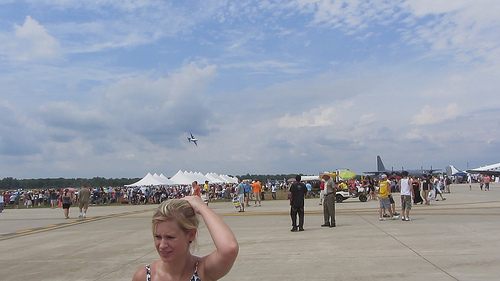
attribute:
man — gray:
[374, 172, 398, 221]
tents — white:
[127, 165, 243, 188]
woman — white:
[130, 192, 240, 279]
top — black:
[143, 256, 202, 279]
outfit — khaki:
[75, 175, 110, 220]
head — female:
[148, 197, 200, 264]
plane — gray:
[364, 156, 446, 179]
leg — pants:
[288, 206, 298, 232]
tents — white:
[135, 169, 247, 189]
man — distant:
[289, 170, 314, 234]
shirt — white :
[400, 177, 411, 194]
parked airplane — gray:
[363, 154, 441, 182]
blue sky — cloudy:
[184, 129, 201, 149]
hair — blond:
[158, 197, 195, 228]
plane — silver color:
[185, 129, 198, 148]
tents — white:
[131, 165, 238, 204]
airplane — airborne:
[147, 120, 204, 155]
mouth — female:
[156, 247, 176, 257]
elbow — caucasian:
[212, 232, 232, 279]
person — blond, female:
[104, 197, 241, 279]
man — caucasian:
[390, 176, 433, 232]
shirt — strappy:
[182, 259, 203, 278]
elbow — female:
[218, 234, 243, 254]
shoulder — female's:
[132, 257, 158, 276]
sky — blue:
[171, 33, 237, 86]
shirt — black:
[289, 181, 308, 223]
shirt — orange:
[252, 179, 266, 199]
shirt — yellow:
[377, 180, 390, 197]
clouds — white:
[117, 59, 220, 133]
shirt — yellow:
[373, 177, 393, 197]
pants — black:
[289, 200, 309, 230]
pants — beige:
[322, 192, 338, 223]